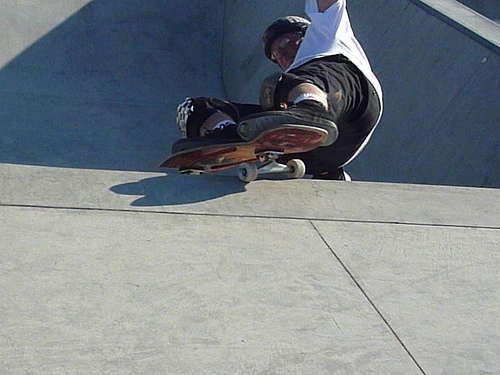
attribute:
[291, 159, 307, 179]
wheel — white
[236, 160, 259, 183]
wheel — white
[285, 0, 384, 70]
shirt — white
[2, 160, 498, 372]
ramp — gray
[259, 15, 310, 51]
helmet — black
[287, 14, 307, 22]
lettering — white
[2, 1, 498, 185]
wall — blue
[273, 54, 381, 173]
shorts — black 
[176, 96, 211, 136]
knee pad — black , white 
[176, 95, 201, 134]
knee pad — black , white , checkered  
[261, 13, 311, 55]
helmet — black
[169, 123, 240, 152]
shoe — black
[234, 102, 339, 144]
shoe — black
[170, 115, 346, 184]
skateboard — red, yellow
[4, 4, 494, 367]
wall — cement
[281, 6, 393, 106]
shirt — white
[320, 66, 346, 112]
pants — black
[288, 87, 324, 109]
socks — white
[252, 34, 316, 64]
glasses — clear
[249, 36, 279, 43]
helmet — black